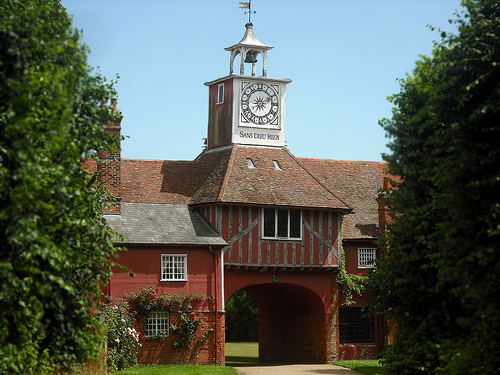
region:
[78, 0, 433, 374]
a building between the trees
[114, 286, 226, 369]
a climbing rose on the building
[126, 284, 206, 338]
red roses on the climbing plant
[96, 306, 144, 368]
a pink rosebush by the building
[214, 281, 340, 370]
an arch in the building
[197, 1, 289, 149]
a clock tower on top of the building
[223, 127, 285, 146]
a French slogan on the clock tower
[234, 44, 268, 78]
a bell in the tower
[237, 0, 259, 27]
a weathervane on top of the tower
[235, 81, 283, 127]
a clock face on the tower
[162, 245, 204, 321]
part of a window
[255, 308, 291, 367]
part of a space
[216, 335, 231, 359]
edge of a wall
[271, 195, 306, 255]
part of a window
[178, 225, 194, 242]
edge of a roof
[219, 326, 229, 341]
edge of a wall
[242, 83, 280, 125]
white face of the clock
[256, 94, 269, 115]
black hands of the clock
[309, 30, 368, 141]
clear blue skies over the scene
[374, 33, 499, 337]
trees growing to the right of the building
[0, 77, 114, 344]
trees growing to the left of the building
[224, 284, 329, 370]
brick tunnel of the building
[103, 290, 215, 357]
rose bushes growing around the window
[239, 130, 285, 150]
black lettering on the white clock tower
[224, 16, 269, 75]
bell tower on top of the building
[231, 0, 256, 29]
metal wind meter on top of the building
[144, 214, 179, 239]
the roof is gray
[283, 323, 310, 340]
the building is made of bricks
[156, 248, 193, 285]
the window has bars on it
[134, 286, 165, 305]
the flowers are red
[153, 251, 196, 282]
the window is white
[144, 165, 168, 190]
the roof is brown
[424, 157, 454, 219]
the tree has green leaves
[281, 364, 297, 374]
the road is tan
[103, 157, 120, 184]
the chimney is made of bricks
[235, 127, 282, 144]
the words are black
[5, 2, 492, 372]
Exterior shot, daytime, season, probably before late fall, winter.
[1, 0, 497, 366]
Exterior shot, building in country, surrounded by manipulated landscape.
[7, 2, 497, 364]
Very tall, green clipped hedges, acting as gate.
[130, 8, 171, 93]
Porcelain blue sky.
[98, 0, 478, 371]
Rustic, country-style church.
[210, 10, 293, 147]
White steeple, with bell and clockface.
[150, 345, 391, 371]
Manicured lawn and pathway.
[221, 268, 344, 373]
Archway, over pathway.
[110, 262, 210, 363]
Rosebush and vine, surrounding one of the many-paned windows.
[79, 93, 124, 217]
One of two, old-fashioned brick chimneys.